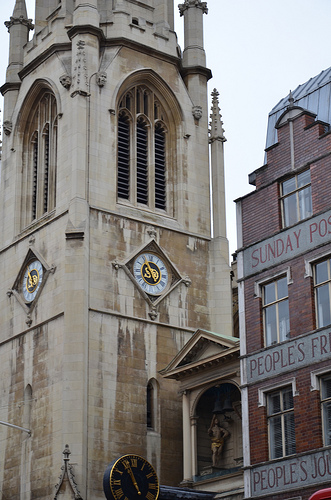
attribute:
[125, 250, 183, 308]
clock — gold, big, numbered, blue, roman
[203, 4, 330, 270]
sky — blue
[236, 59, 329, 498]
building — part, stone, brick, church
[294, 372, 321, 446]
wall — brown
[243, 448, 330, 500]
sign — part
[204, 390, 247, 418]
bell — hanging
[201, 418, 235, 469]
statue — person